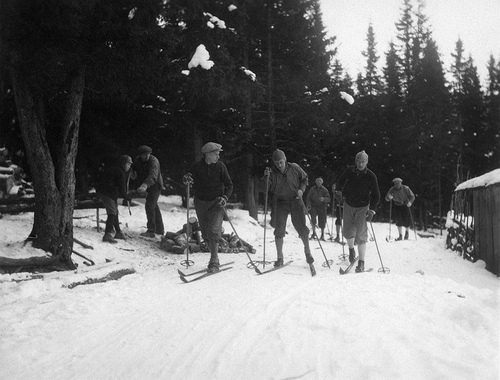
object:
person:
[331, 148, 381, 272]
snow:
[1, 194, 499, 380]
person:
[256, 148, 314, 268]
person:
[183, 141, 235, 274]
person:
[384, 178, 415, 241]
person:
[306, 175, 332, 240]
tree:
[390, 0, 415, 114]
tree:
[409, 1, 434, 91]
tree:
[248, 0, 294, 168]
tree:
[220, 32, 267, 224]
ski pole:
[370, 222, 390, 275]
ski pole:
[336, 200, 350, 262]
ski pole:
[300, 200, 324, 268]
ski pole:
[256, 167, 273, 270]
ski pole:
[222, 206, 261, 272]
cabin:
[452, 166, 499, 278]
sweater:
[184, 156, 234, 203]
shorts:
[341, 202, 369, 246]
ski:
[256, 261, 291, 275]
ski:
[308, 263, 316, 277]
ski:
[339, 255, 359, 275]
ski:
[354, 267, 372, 273]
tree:
[0, 0, 188, 273]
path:
[1, 215, 499, 379]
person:
[97, 154, 132, 241]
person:
[130, 145, 165, 239]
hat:
[200, 141, 223, 155]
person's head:
[201, 141, 223, 165]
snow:
[186, 43, 216, 71]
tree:
[140, 1, 193, 203]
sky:
[272, 0, 499, 100]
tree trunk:
[193, 126, 205, 163]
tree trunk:
[244, 153, 259, 221]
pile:
[159, 216, 257, 255]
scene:
[1, 1, 500, 378]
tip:
[179, 274, 190, 282]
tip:
[255, 268, 264, 274]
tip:
[340, 268, 348, 276]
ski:
[177, 261, 234, 278]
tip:
[177, 269, 188, 276]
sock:
[347, 237, 355, 248]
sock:
[358, 243, 366, 263]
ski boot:
[348, 247, 356, 262]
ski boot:
[356, 260, 365, 272]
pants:
[145, 182, 165, 234]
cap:
[135, 145, 153, 156]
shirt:
[201, 159, 216, 169]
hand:
[263, 167, 271, 177]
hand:
[295, 190, 304, 200]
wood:
[0, 190, 149, 206]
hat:
[271, 148, 287, 162]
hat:
[354, 149, 368, 165]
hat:
[117, 155, 132, 165]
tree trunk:
[7, 50, 86, 256]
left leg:
[340, 202, 357, 264]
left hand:
[182, 172, 194, 188]